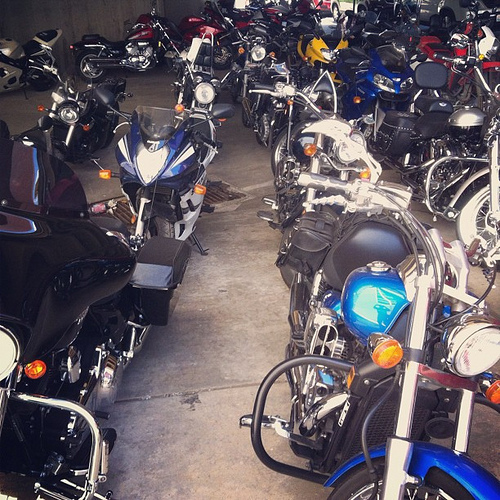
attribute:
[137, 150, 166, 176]
motorcycle — yellow, blue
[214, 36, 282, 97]
motorcycle — red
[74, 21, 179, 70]
motorcycle — red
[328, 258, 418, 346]
motorcycle — blue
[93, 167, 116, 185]
turn signal — yellow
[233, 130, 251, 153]
floor — cement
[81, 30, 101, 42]
seat — leather, black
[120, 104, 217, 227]
cycle — black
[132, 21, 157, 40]
compartment — red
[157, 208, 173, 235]
gas tank — red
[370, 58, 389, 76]
stripes — blue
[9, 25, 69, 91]
bike — full dress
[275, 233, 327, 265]
box — black